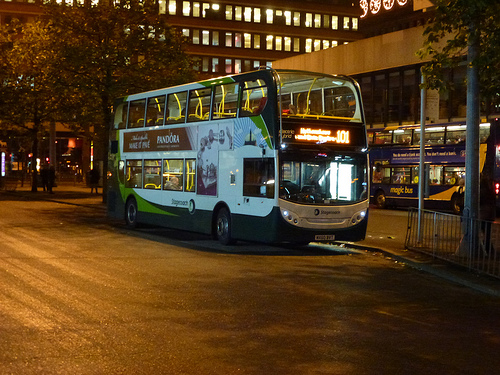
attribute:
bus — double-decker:
[91, 65, 376, 246]